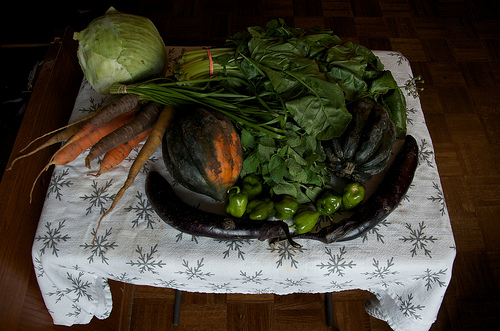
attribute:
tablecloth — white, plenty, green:
[21, 15, 442, 246]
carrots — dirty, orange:
[11, 82, 172, 233]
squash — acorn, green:
[157, 109, 249, 201]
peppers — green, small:
[228, 180, 369, 241]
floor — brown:
[450, 9, 498, 278]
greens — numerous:
[240, 17, 413, 137]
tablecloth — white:
[72, 69, 460, 318]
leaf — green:
[270, 76, 359, 138]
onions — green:
[104, 75, 296, 142]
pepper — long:
[144, 168, 288, 247]